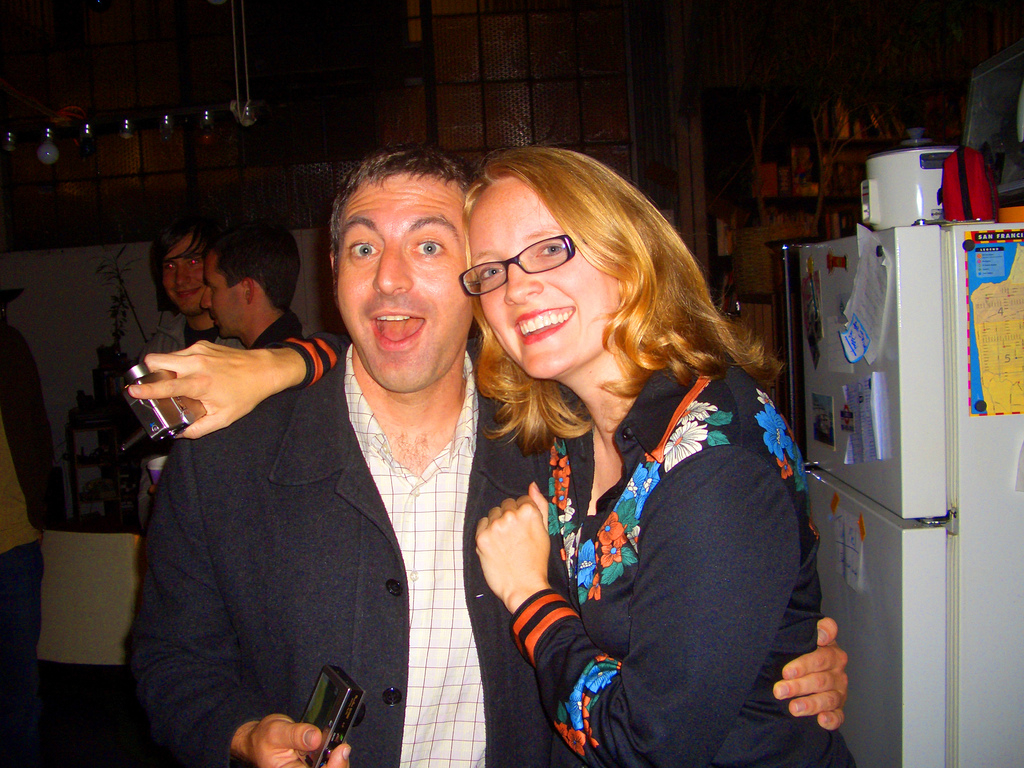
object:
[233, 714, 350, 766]
hand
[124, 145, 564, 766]
man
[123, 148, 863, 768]
woman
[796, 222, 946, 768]
door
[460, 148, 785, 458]
hair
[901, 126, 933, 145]
lid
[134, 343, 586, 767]
jacket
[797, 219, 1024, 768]
fridge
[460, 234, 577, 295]
eyeglasses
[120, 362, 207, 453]
camera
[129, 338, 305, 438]
hand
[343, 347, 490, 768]
shirt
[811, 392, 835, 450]
magnets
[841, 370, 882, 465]
paper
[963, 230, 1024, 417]
magnet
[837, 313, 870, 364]
magnet